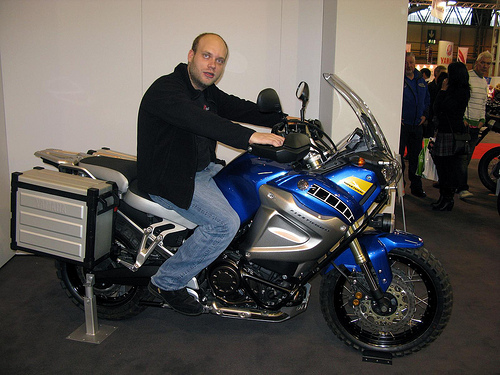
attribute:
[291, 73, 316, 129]
mirror — side view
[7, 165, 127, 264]
box — silver, saddle box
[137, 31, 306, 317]
man — sitting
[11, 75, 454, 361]
motorcycle — showcase, blue, silver, demo, blue and silver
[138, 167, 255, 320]
jeans — blue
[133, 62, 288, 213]
jacket — blue, sports , black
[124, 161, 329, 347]
jeans — blue, faded, denim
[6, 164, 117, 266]
box — silver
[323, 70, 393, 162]
windshield — clear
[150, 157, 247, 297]
jeans — blue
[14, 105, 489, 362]
motorcycle — blue, silver, stationary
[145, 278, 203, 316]
shoe — black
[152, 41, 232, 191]
man — black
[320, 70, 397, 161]
visor — clear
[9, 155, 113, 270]
cases — silver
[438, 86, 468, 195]
clothing — dark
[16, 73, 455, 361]
motorcylce — silver, blue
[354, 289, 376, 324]
spokes — chrome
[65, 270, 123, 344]
stand — silver, supporting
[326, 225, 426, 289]
fender — blue